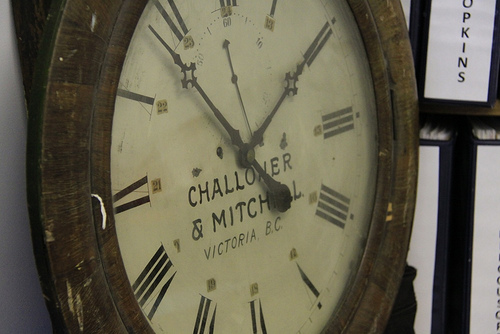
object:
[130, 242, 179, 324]
number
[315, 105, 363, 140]
number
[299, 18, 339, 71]
number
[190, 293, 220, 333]
number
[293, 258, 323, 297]
number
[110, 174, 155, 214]
number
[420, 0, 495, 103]
paper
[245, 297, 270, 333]
roman number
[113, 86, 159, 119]
number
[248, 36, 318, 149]
hand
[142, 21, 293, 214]
minute hand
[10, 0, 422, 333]
clock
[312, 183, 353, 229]
number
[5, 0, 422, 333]
frame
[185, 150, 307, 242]
clock maker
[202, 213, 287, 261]
location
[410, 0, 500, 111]
binder